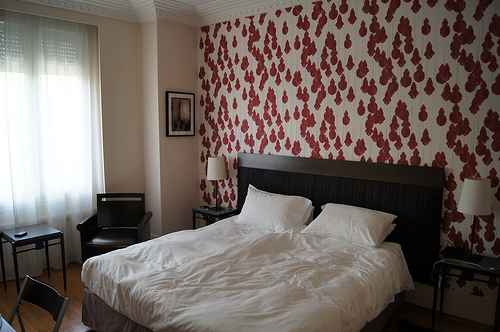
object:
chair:
[76, 193, 153, 265]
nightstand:
[431, 250, 500, 331]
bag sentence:
[168, 158, 450, 318]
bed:
[81, 153, 445, 332]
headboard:
[236, 153, 446, 287]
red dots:
[298, 54, 403, 126]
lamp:
[207, 156, 227, 180]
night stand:
[192, 204, 237, 230]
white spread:
[80, 213, 412, 330]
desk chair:
[6, 274, 70, 332]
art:
[165, 91, 195, 137]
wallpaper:
[197, 0, 498, 259]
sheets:
[81, 215, 416, 331]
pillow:
[233, 184, 312, 234]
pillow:
[299, 202, 398, 246]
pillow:
[319, 223, 397, 249]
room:
[0, 0, 500, 332]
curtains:
[0, 9, 105, 281]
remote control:
[15, 231, 28, 237]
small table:
[0, 223, 68, 295]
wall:
[261, 0, 499, 120]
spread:
[81, 214, 417, 332]